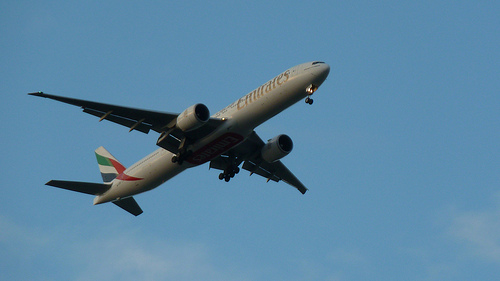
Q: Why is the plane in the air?
A: To get to a destination.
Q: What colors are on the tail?
A: Green blue and red.